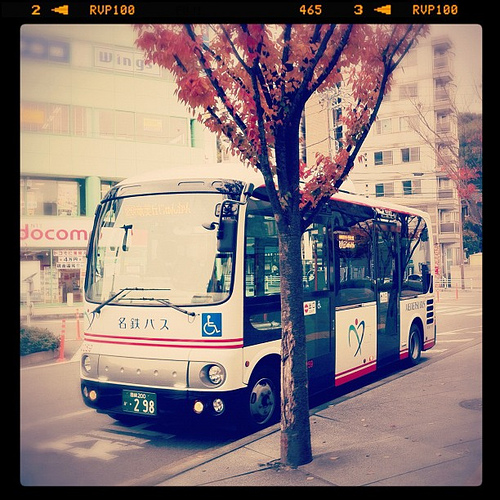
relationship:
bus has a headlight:
[78, 176, 436, 432] [206, 364, 223, 385]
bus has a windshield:
[78, 176, 436, 432] [89, 194, 240, 307]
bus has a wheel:
[78, 176, 436, 432] [407, 326, 422, 361]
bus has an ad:
[78, 176, 436, 432] [334, 299, 380, 386]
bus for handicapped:
[78, 176, 436, 432] [201, 313, 222, 338]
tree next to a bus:
[133, 27, 431, 463] [78, 176, 436, 432]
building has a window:
[338, 24, 465, 285] [397, 112, 420, 134]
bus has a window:
[78, 176, 436, 432] [400, 216, 430, 296]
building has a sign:
[338, 24, 465, 285] [20, 216, 95, 248]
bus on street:
[78, 176, 436, 432] [21, 300, 482, 485]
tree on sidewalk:
[133, 27, 431, 463] [162, 347, 484, 488]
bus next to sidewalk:
[78, 176, 436, 432] [162, 347, 484, 488]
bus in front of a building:
[78, 176, 436, 432] [338, 24, 465, 285]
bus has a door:
[78, 176, 436, 432] [375, 223, 400, 371]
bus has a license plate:
[78, 176, 436, 432] [121, 389, 157, 418]